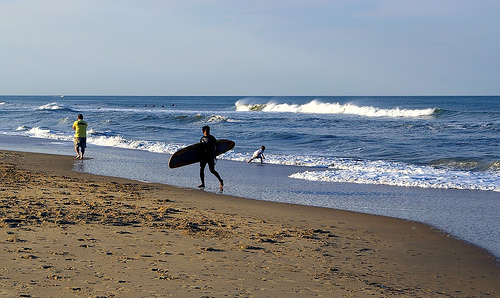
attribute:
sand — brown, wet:
[56, 230, 84, 247]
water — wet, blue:
[367, 131, 403, 140]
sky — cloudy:
[245, 25, 279, 39]